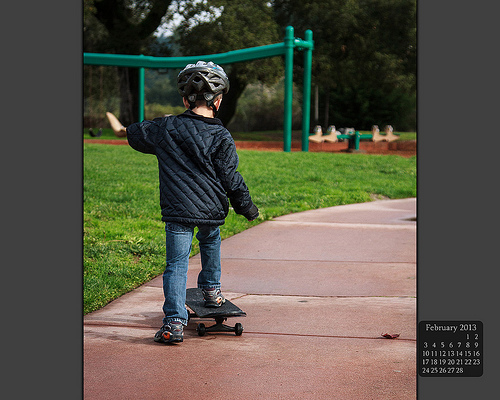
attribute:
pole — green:
[297, 27, 317, 154]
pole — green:
[277, 22, 295, 153]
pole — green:
[135, 51, 147, 126]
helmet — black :
[174, 60, 229, 107]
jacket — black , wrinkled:
[127, 116, 259, 224]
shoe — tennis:
[101, 260, 310, 380]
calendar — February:
[422, 303, 492, 378]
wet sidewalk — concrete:
[85, 194, 415, 398]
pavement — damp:
[119, 177, 423, 396]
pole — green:
[301, 30, 313, 151]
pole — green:
[281, 25, 295, 149]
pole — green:
[138, 52, 145, 119]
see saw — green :
[308, 119, 405, 150]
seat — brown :
[326, 125, 340, 147]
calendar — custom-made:
[415, 317, 483, 377]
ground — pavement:
[258, 221, 378, 389]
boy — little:
[107, 63, 276, 345]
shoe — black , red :
[152, 290, 229, 343]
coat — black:
[120, 108, 256, 234]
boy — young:
[124, 55, 263, 354]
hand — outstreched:
[94, 105, 135, 144]